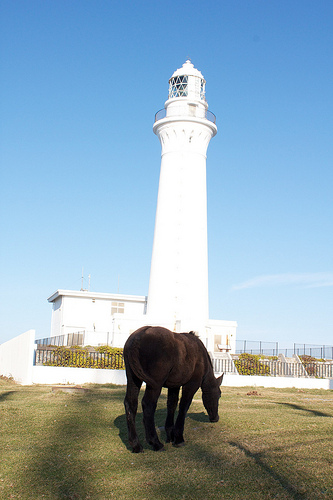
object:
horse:
[123, 325, 224, 453]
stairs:
[212, 350, 228, 355]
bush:
[234, 351, 271, 374]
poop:
[236, 388, 262, 395]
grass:
[0, 375, 332, 497]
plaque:
[217, 343, 231, 350]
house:
[47, 287, 149, 347]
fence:
[235, 338, 278, 356]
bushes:
[41, 344, 126, 369]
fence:
[294, 342, 332, 359]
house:
[208, 318, 237, 354]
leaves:
[249, 364, 251, 368]